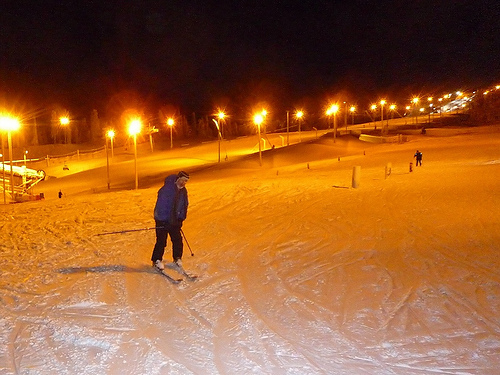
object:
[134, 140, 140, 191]
pole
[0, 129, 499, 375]
ground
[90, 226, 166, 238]
ski pole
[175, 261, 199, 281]
ski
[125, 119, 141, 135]
light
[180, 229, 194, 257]
pole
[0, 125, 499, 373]
hill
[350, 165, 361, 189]
post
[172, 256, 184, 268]
ski shoe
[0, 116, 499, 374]
snow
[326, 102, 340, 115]
light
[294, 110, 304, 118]
light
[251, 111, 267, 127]
light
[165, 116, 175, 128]
light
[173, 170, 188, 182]
hat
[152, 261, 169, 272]
white boots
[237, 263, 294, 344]
tracks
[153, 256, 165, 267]
foot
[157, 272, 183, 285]
ski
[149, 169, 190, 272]
man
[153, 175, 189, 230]
jacket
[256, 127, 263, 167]
poles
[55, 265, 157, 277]
shadow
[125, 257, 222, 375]
tracks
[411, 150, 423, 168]
person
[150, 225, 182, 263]
black pants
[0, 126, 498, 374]
slope